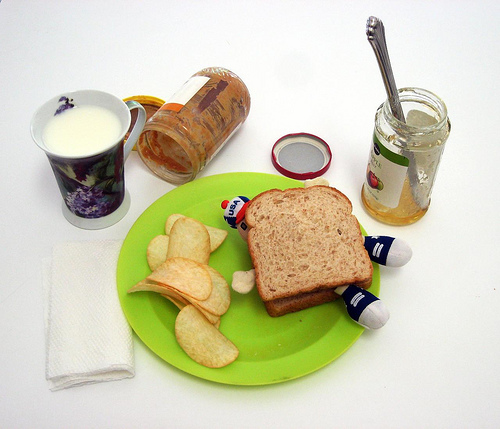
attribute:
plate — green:
[116, 171, 383, 389]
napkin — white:
[43, 243, 142, 394]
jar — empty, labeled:
[136, 57, 259, 187]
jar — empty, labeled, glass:
[356, 84, 456, 234]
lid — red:
[268, 126, 344, 183]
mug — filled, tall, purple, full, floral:
[25, 87, 152, 237]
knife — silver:
[363, 13, 429, 210]